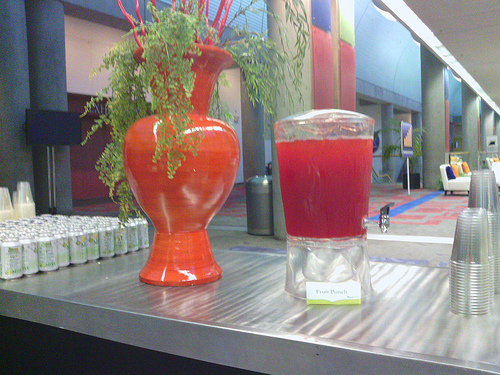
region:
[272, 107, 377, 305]
a cooler filled with a red liquid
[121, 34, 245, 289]
a large orange vase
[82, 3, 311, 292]
a large orange vase with a plant in it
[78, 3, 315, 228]
green frond of a plant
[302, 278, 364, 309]
a small label in front of cooler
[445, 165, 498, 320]
stacks of plastic cups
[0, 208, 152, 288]
white cans next to orange vase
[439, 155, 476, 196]
white couch with pillows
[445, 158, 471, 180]
pillows are blue, orange and green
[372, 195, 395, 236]
spout of cooler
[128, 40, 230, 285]
An orange vase with plants in it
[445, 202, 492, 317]
Stack of clear cups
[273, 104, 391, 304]
A jug of red drink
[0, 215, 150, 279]
White cans on a table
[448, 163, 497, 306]
Stacks of clear, plastic cups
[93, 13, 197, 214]
Leaves dangling from the potted plant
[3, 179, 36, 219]
Stack of plastic cups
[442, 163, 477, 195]
A white lounge chair with color pillow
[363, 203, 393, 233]
A small, clear spigot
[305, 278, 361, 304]
A white and green card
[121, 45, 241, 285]
one large shiny orange vase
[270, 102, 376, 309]
one cylindrical glass container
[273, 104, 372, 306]
red liquid in glass container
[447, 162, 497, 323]
stacks of clear plastic cups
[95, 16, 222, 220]
greenery spilling down side of orange vase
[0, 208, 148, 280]
little white cans on stainless steel table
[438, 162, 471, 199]
one white chair with blue pillow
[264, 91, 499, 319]
drink container next to cups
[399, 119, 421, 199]
blue and yellow sign on metal pole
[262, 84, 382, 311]
glass on the table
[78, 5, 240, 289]
vase on the table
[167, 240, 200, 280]
the vase is orange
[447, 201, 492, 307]
stack of paper cups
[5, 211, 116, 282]
row of soda cans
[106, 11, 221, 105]
plant in the vase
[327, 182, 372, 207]
red drink in glass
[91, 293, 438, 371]
The counter is the color silver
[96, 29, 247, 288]
A vase sitting on the counter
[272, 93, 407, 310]
A pitcher of juice on the counter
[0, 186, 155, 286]
A large amount of cans on the counter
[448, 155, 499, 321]
Plastic cups on the counter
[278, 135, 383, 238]
The juice is the color red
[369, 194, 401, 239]
The juice spout on the container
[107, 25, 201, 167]
The leaves are the color green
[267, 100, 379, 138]
The top to the pitcher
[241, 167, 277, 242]
A trash can on the ground